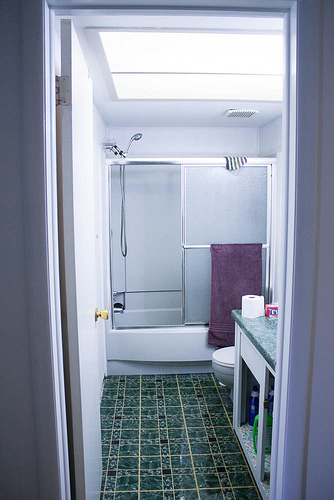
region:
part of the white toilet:
[209, 346, 237, 392]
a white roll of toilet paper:
[241, 293, 263, 318]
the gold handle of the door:
[95, 309, 109, 320]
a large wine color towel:
[210, 246, 259, 342]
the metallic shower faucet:
[109, 134, 141, 255]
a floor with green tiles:
[108, 374, 251, 498]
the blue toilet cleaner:
[251, 387, 256, 420]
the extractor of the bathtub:
[227, 109, 256, 119]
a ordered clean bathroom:
[66, 70, 309, 494]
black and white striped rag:
[218, 150, 259, 185]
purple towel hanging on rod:
[197, 220, 265, 346]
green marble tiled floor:
[143, 407, 206, 492]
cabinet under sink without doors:
[221, 377, 298, 468]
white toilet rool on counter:
[241, 277, 262, 330]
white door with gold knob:
[76, 35, 123, 490]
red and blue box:
[256, 282, 277, 322]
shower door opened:
[117, 169, 282, 373]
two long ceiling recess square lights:
[100, 25, 279, 137]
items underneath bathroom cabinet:
[248, 411, 285, 481]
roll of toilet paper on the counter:
[241, 292, 266, 319]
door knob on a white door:
[93, 303, 112, 323]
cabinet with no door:
[232, 317, 274, 498]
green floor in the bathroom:
[98, 366, 264, 498]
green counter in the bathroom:
[230, 305, 286, 367]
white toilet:
[212, 339, 240, 400]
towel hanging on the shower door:
[206, 236, 266, 347]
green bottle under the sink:
[251, 406, 274, 457]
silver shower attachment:
[106, 126, 144, 264]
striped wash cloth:
[224, 151, 250, 170]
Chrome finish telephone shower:
[96, 130, 142, 257]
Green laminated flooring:
[105, 375, 254, 499]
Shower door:
[109, 157, 274, 327]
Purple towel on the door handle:
[204, 235, 266, 349]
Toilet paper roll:
[237, 294, 267, 316]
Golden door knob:
[91, 303, 109, 323]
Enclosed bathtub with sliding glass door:
[99, 122, 274, 362]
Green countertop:
[231, 308, 283, 370]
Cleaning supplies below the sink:
[237, 361, 274, 472]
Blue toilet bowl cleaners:
[246, 377, 273, 427]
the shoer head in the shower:
[125, 125, 142, 156]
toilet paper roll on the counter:
[240, 290, 267, 317]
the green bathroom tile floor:
[110, 376, 204, 484]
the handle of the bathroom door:
[92, 304, 110, 324]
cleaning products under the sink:
[246, 387, 274, 457]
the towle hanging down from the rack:
[205, 240, 266, 344]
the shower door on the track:
[179, 163, 265, 326]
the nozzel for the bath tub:
[114, 303, 129, 314]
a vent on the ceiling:
[224, 107, 254, 124]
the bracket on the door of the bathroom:
[50, 72, 70, 106]